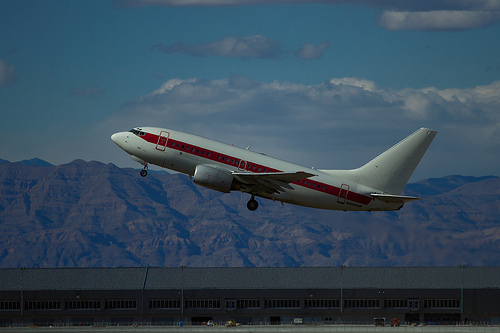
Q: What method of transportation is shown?
A: Airplane.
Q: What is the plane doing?
A: Taking off.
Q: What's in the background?
A: Mountains.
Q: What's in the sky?
A: Clouds.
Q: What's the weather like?
A: Cloudy.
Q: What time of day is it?
A: Evening.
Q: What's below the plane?
A: A building.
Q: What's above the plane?
A: Sky.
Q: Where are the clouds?
A: In the sky.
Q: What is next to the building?
A: Mountain.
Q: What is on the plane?
A: Red stripe.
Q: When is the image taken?
A: Plane is taking off.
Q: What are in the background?
A: Hills.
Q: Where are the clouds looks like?
A: In sky.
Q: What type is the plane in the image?
A: Commercial.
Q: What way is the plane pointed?
A: Toward the sky.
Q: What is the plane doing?
A: Taking off.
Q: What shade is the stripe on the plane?
A: Red.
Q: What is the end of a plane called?
A: The tail.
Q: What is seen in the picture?
A: Aeroplane.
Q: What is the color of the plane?
A: White and red.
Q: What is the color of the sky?
A: Blue.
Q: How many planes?
A: 1.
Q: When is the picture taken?
A: Daytime.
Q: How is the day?
A: Cloudy.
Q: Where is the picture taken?
A: At an airport.